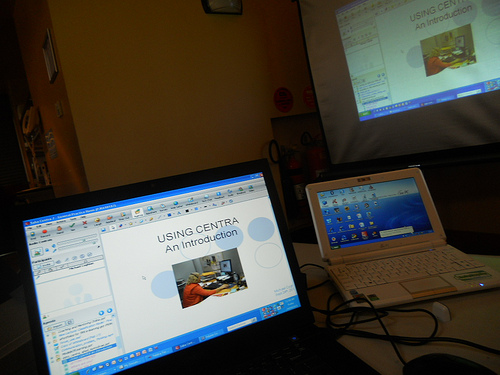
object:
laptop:
[305, 167, 500, 309]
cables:
[317, 326, 500, 354]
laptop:
[10, 157, 382, 375]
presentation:
[381, 1, 500, 85]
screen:
[334, 0, 499, 122]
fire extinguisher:
[269, 139, 312, 218]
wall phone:
[21, 104, 45, 168]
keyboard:
[329, 247, 485, 291]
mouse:
[401, 353, 496, 375]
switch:
[54, 100, 63, 119]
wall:
[9, 1, 92, 204]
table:
[3, 241, 499, 375]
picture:
[41, 27, 57, 84]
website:
[31, 181, 296, 373]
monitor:
[5, 158, 314, 375]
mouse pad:
[399, 275, 454, 295]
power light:
[479, 282, 485, 287]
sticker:
[274, 86, 295, 113]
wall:
[49, 0, 332, 191]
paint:
[35, 4, 37, 8]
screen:
[316, 178, 435, 250]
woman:
[182, 271, 230, 308]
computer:
[216, 259, 241, 285]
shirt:
[182, 283, 216, 307]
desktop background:
[319, 181, 427, 235]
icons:
[337, 216, 344, 223]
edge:
[303, 156, 417, 189]